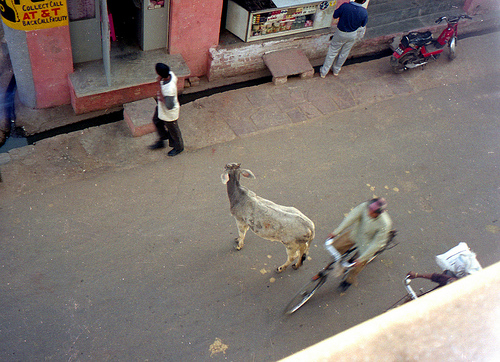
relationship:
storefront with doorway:
[2, 0, 228, 122] [95, 1, 159, 61]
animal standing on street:
[216, 157, 316, 274] [1, 92, 499, 284]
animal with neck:
[216, 157, 316, 274] [225, 178, 245, 208]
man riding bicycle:
[148, 61, 183, 158] [283, 228, 402, 316]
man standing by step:
[148, 61, 190, 158] [123, 97, 159, 128]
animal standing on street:
[216, 157, 316, 274] [13, 143, 470, 324]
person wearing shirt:
[315, 0, 370, 80] [331, 2, 368, 30]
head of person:
[362, 194, 392, 219] [319, 194, 392, 297]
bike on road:
[388, 14, 472, 75] [0, 22, 500, 360]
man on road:
[148, 61, 190, 158] [0, 22, 497, 360]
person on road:
[319, 194, 392, 297] [61, 164, 453, 349]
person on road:
[321, 0, 371, 78] [0, 22, 497, 360]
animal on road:
[216, 157, 316, 274] [0, 22, 497, 360]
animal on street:
[192, 157, 316, 287] [3, 64, 498, 359]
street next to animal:
[48, 184, 209, 319] [211, 146, 316, 271]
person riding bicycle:
[319, 194, 392, 297] [277, 229, 401, 314]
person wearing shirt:
[302, 174, 392, 297] [339, 196, 394, 260]